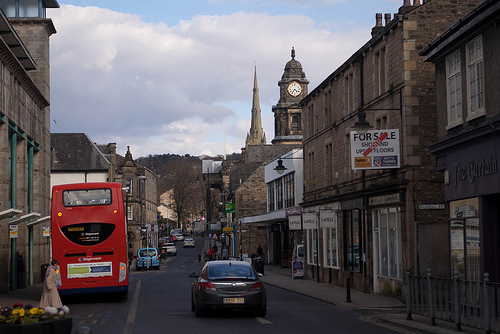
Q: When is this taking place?
A: Daytime.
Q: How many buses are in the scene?
A: One.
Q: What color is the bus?
A: Red.